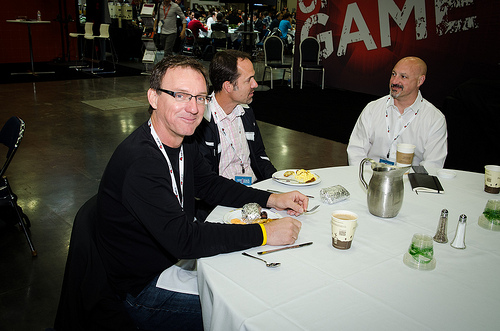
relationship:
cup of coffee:
[333, 214, 358, 253] [362, 160, 403, 224]